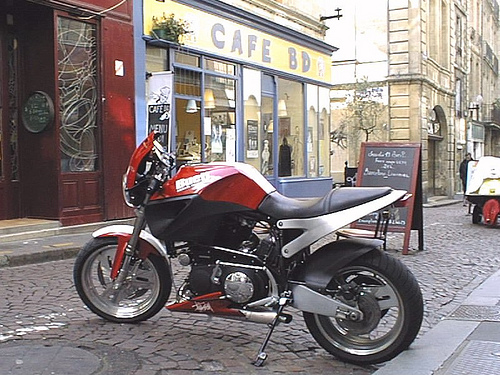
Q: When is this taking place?
A: Daytime.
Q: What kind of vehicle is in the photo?
A: Motorcycle.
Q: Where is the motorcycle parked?
A: Street.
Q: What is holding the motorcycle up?
A: Kickstand.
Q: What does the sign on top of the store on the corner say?
A: Cafe bd.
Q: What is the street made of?
A: Bricks.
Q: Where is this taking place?
A: On a very narrow street in a city.